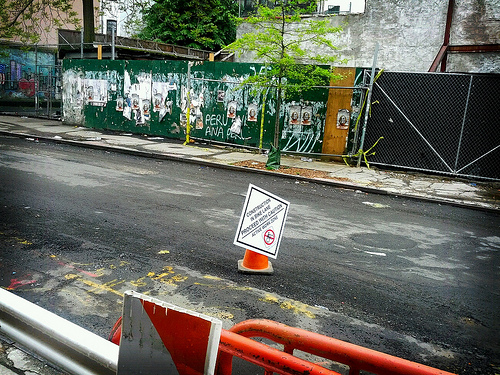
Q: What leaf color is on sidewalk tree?
A: Bright green.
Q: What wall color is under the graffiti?
A: Green.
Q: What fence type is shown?
A: Chain link and wooden.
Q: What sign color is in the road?
A: White, black and red.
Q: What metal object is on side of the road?
A: Guard rail.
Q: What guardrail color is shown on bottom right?
A: Orange.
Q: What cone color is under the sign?
A: Orange and black.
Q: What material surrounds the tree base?
A: Mulch.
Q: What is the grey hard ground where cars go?
A: Road.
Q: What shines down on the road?
A: Sun.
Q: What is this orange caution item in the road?
A: Caution cone.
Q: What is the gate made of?
A: Metal.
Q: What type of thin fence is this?
A: Chain link.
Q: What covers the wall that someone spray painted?
A: Graffiti.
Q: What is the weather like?
A: Gloomy.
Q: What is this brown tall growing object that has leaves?
A: Tree.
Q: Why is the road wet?
A: Rain.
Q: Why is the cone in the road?
A: Road work is being done.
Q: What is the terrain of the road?
A: Asphalt.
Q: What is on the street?
A: Cone.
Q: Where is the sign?
A: On the cone.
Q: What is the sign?
A: Warning.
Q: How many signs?
A: 1.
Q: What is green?
A: The wall.